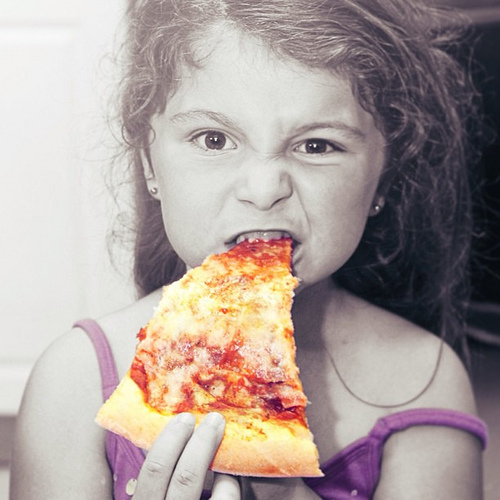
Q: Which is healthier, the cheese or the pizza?
A: The cheese is healthier than the pizza.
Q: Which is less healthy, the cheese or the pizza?
A: The pizza is less healthy than the cheese.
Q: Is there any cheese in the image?
A: Yes, there is cheese.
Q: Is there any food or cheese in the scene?
A: Yes, there is cheese.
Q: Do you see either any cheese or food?
A: Yes, there is cheese.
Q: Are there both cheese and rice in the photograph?
A: No, there is cheese but no rice.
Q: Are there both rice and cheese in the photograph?
A: No, there is cheese but no rice.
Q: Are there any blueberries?
A: No, there are no blueberries.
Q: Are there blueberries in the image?
A: No, there are no blueberries.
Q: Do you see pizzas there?
A: Yes, there is a pizza.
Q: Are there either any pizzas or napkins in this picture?
A: Yes, there is a pizza.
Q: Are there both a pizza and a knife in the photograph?
A: No, there is a pizza but no knives.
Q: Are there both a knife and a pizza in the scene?
A: No, there is a pizza but no knives.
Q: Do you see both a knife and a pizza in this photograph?
A: No, there is a pizza but no knives.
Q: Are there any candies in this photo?
A: No, there are no candies.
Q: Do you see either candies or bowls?
A: No, there are no candies or bowls.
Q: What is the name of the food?
A: The food is a pizza.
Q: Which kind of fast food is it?
A: The food is a pizza.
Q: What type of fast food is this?
A: This is a pizza.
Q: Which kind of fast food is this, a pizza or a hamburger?
A: This is a pizza.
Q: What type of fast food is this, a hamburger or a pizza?
A: This is a pizza.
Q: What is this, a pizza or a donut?
A: This is a pizza.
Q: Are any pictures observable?
A: No, there are no pictures.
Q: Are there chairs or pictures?
A: No, there are no pictures or chairs.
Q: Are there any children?
A: Yes, there is a child.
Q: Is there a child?
A: Yes, there is a child.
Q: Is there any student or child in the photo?
A: Yes, there is a child.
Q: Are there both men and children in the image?
A: No, there is a child but no men.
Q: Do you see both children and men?
A: No, there is a child but no men.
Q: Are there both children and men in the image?
A: No, there is a child but no men.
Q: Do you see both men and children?
A: No, there is a child but no men.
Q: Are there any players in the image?
A: No, there are no players.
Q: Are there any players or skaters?
A: No, there are no players or skaters.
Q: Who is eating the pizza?
A: The kid is eating the pizza.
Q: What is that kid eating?
A: The kid is eating a pizza.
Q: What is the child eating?
A: The kid is eating a pizza.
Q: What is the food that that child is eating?
A: The food is a pizza.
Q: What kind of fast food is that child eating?
A: The child is eating a pizza.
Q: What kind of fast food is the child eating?
A: The child is eating a pizza.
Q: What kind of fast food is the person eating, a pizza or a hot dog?
A: The child is eating a pizza.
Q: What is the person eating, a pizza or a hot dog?
A: The child is eating a pizza.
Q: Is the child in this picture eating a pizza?
A: Yes, the child is eating a pizza.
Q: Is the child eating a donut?
A: No, the child is eating a pizza.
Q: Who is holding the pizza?
A: The kid is holding the pizza.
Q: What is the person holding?
A: The kid is holding the pizza.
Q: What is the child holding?
A: The kid is holding the pizza.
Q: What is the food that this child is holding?
A: The food is a pizza.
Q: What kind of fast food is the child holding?
A: The child is holding the pizza.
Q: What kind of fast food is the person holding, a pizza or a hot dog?
A: The child is holding a pizza.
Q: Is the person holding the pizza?
A: Yes, the child is holding the pizza.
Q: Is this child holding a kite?
A: No, the child is holding the pizza.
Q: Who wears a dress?
A: The kid wears a dress.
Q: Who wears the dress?
A: The kid wears a dress.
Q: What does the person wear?
A: The child wears a dress.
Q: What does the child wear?
A: The child wears a dress.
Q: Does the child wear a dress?
A: Yes, the child wears a dress.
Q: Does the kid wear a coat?
A: No, the kid wears a dress.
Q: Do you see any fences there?
A: No, there are no fences.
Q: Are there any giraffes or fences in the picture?
A: No, there are no fences or giraffes.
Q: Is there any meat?
A: No, there is no meat.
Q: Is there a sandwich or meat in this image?
A: No, there are no meat or sandwiches.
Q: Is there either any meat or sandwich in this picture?
A: No, there are no meat or sandwiches.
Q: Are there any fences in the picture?
A: No, there are no fences.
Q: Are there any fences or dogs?
A: No, there are no fences or dogs.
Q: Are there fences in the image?
A: No, there are no fences.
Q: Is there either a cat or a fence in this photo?
A: No, there are no fences or cats.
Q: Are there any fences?
A: No, there are no fences.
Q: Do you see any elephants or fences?
A: No, there are no fences or elephants.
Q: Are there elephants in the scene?
A: No, there are no elephants.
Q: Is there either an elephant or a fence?
A: No, there are no elephants or fences.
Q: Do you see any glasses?
A: No, there are no glasses.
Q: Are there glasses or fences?
A: No, there are no glasses or fences.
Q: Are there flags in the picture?
A: No, there are no flags.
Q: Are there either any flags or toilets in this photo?
A: No, there are no flags or toilets.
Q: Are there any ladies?
A: No, there are no ladies.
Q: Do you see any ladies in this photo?
A: No, there are no ladies.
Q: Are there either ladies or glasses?
A: No, there are no ladies or glasses.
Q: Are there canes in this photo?
A: No, there are no canes.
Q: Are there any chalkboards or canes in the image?
A: No, there are no canes or chalkboards.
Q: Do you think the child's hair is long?
A: Yes, the hair is long.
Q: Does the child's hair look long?
A: Yes, the hair is long.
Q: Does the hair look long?
A: Yes, the hair is long.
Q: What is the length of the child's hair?
A: The hair is long.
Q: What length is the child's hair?
A: The hair is long.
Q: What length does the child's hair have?
A: The hair has long length.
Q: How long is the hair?
A: The hair is long.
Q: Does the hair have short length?
A: No, the hair is long.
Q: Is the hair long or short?
A: The hair is long.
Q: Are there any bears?
A: No, there are no bears.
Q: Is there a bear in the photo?
A: No, there are no bears.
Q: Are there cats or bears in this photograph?
A: No, there are no bears or cats.